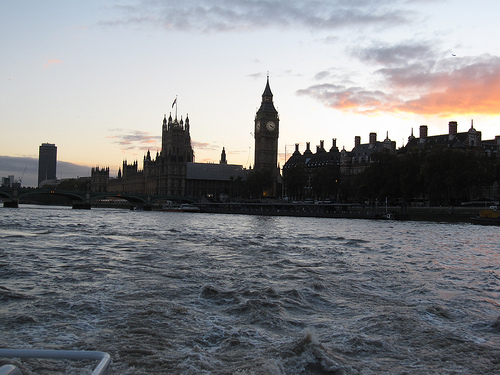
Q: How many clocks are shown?
A: 1.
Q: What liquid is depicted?
A: Water.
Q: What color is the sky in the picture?
A: Blue, pink, and yellow.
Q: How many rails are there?
A: 1.